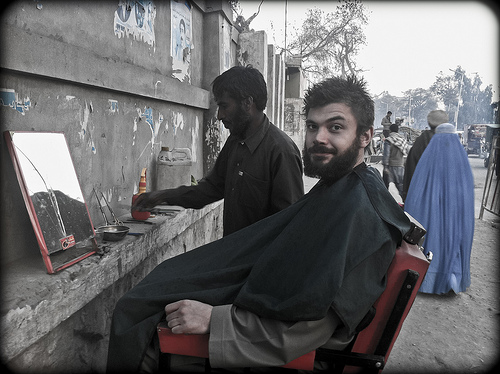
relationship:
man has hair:
[105, 73, 411, 373] [298, 75, 375, 154]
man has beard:
[105, 73, 411, 373] [301, 135, 360, 181]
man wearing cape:
[105, 73, 411, 373] [103, 164, 411, 374]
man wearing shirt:
[105, 73, 411, 373] [208, 303, 359, 369]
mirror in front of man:
[3, 131, 100, 275] [105, 73, 411, 373]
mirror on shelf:
[3, 131, 100, 275] [0, 197, 224, 367]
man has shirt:
[131, 63, 306, 238] [170, 112, 305, 238]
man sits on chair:
[105, 73, 411, 373] [158, 211, 433, 374]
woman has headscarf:
[404, 123, 475, 296] [404, 123, 474, 298]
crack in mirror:
[13, 144, 66, 237] [3, 131, 100, 275]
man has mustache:
[105, 73, 411, 373] [308, 146, 337, 154]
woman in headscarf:
[404, 123, 475, 296] [404, 123, 474, 298]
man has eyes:
[105, 73, 411, 373] [306, 123, 342, 131]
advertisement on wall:
[171, 1, 193, 84] [0, 0, 203, 266]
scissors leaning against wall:
[100, 191, 124, 226] [0, 0, 203, 266]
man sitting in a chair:
[105, 73, 411, 373] [158, 211, 433, 374]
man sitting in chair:
[105, 73, 411, 373] [158, 211, 433, 374]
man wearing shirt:
[131, 63, 306, 238] [170, 112, 305, 238]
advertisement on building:
[171, 1, 193, 84] [0, 0, 325, 373]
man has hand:
[105, 73, 411, 373] [163, 299, 215, 335]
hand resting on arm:
[163, 299, 215, 335] [156, 322, 384, 373]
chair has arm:
[158, 211, 433, 374] [156, 322, 384, 373]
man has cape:
[105, 73, 411, 373] [103, 164, 411, 374]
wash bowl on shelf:
[98, 227, 131, 241] [0, 197, 224, 367]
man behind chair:
[131, 63, 306, 238] [158, 211, 433, 374]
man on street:
[105, 73, 411, 373] [302, 153, 499, 373]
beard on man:
[301, 135, 360, 181] [105, 73, 411, 373]